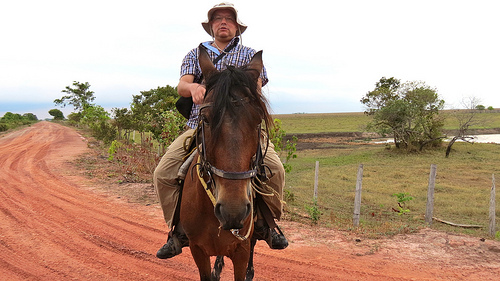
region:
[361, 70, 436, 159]
a tree in a distance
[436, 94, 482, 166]
a tree in a distance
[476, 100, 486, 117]
a tree in a distance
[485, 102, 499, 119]
a tree in a distance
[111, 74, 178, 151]
a tree in a distance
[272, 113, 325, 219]
a tree in a distance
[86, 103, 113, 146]
a tree in a distance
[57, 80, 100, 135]
a tree in a distance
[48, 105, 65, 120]
a tree in a distance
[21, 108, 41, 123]
a tree in a distance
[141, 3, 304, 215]
man riding horse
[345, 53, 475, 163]
trees next to path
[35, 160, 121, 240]
red dirt on ground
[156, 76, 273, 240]
brown horse carrying man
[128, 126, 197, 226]
brown pants on man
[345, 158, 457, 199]
green grass next to path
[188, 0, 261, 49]
hat on man's head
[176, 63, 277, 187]
horse with black hair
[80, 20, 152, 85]
white sky in the background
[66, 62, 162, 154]
trees behind the rider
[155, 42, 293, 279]
brown horse on clay dirt road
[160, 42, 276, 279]
brown horse carrying fat man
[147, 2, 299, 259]
man in hat, blue plaid shirt and khaki pants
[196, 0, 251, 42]
light weight hat of man riding horse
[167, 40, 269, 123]
blue plaid shirt of man riding horse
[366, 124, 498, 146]
small body of water in field to the right of the horse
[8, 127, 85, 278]
clay colored dirt road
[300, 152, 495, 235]
fence with wooden poles to the right of the horse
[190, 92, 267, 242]
halter and reins on the horse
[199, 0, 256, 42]
the head of a person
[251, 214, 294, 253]
the foot of the person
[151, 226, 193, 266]
a dark brown shoe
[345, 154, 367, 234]
a wooden fence post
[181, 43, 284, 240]
the head of a horse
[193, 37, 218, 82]
the ear of a horse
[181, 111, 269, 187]
the bridle of a horse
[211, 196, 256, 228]
the nose of a horse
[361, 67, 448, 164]
a green tree on the grass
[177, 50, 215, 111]
the arm of a person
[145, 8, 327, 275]
man riding brown horse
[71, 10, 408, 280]
man riding brown horse on dirt road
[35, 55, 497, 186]
trees in photograph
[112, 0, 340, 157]
man on horse wearing hat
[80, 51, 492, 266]
man riding horse next to wooden fence poles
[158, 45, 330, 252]
brown horse with someone riding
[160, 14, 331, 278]
brown horse with reins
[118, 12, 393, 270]
man on horse with brown pants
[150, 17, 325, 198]
man on horse with sack on shoulders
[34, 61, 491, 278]
cloudy skies visible in photo